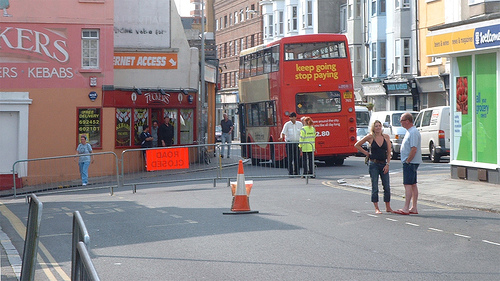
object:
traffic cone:
[222, 158, 259, 214]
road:
[0, 138, 497, 279]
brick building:
[0, 0, 227, 190]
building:
[427, 14, 500, 187]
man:
[219, 113, 233, 160]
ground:
[436, 137, 460, 177]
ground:
[421, 133, 481, 173]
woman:
[296, 114, 320, 172]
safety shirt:
[300, 124, 317, 152]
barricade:
[9, 141, 316, 201]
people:
[355, 120, 393, 214]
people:
[279, 112, 304, 178]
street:
[205, 138, 429, 172]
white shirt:
[401, 126, 424, 163]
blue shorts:
[402, 162, 420, 184]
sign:
[295, 63, 337, 81]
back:
[279, 35, 358, 159]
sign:
[112, 52, 178, 70]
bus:
[231, 34, 357, 168]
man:
[393, 113, 422, 215]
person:
[70, 132, 100, 192]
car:
[402, 106, 452, 163]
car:
[367, 110, 422, 159]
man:
[158, 113, 175, 150]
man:
[152, 119, 161, 153]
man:
[140, 126, 152, 148]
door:
[152, 109, 176, 166]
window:
[278, 34, 345, 62]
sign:
[144, 147, 190, 171]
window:
[296, 91, 344, 114]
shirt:
[369, 133, 388, 160]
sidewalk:
[0, 136, 243, 196]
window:
[451, 52, 485, 171]